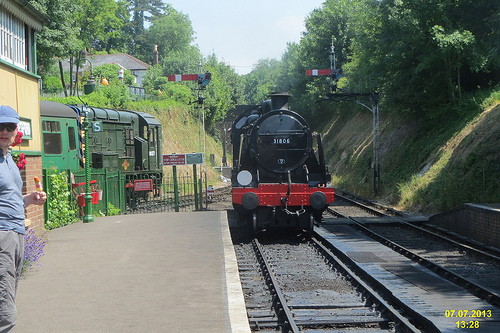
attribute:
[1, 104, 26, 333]
woman — standing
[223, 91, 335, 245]
train — cool, old, black, red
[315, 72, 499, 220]
hill — shady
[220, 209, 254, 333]
line — white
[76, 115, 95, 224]
pole — green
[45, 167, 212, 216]
fence — green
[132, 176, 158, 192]
sign — red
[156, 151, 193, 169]
sign — red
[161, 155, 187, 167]
words — white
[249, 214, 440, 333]
track — black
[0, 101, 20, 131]
hat — blue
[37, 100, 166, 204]
train — black, green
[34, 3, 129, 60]
leaves — green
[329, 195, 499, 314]
track — black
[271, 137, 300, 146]
number — 31806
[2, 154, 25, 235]
shirt — blue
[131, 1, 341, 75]
sky — cloudy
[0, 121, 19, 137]
sunglasses — black